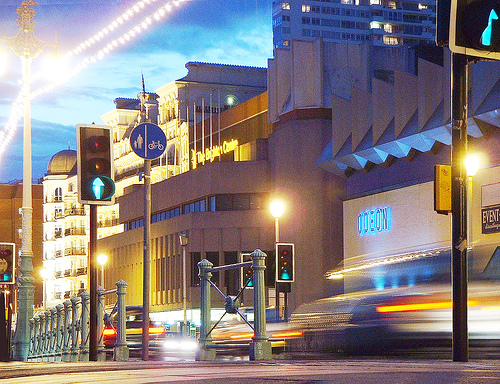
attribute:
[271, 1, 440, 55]
building — white 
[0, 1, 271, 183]
sky — dark blue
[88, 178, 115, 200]
light — green , on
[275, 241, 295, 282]
light — green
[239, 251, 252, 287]
light — green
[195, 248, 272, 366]
fence — decorative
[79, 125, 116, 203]
light — green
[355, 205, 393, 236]
sign — teal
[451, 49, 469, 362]
pole — metal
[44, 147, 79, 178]
roof — rounded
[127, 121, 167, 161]
sign — blue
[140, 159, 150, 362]
pole — metal , gray 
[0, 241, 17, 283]
light — green 